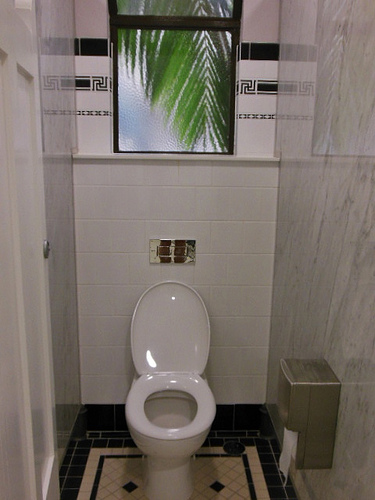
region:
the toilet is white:
[96, 273, 212, 477]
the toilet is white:
[142, 374, 202, 494]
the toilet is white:
[147, 280, 237, 480]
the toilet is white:
[166, 326, 221, 495]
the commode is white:
[126, 246, 218, 497]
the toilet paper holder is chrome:
[275, 338, 345, 494]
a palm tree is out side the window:
[114, 6, 244, 165]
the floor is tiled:
[85, 441, 134, 498]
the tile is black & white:
[84, 445, 134, 496]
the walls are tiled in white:
[87, 222, 128, 295]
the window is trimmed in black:
[102, 10, 248, 173]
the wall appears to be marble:
[310, 141, 364, 336]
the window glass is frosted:
[127, 39, 216, 162]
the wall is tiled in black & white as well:
[76, 23, 110, 146]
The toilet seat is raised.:
[118, 276, 236, 379]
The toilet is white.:
[112, 276, 233, 497]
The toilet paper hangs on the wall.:
[262, 422, 303, 492]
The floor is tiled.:
[193, 413, 294, 499]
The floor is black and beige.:
[192, 421, 283, 498]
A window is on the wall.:
[92, 1, 251, 168]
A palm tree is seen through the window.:
[117, 0, 241, 156]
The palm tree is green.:
[115, 1, 236, 149]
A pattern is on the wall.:
[231, 34, 281, 130]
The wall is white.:
[69, 159, 280, 240]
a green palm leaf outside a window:
[117, 0, 235, 150]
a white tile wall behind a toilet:
[80, 160, 265, 375]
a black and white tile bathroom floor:
[75, 430, 280, 494]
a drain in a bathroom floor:
[218, 436, 248, 453]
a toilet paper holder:
[270, 353, 334, 479]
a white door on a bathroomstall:
[2, 2, 62, 498]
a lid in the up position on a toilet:
[127, 279, 210, 376]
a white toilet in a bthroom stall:
[116, 279, 223, 498]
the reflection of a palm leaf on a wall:
[303, 4, 365, 165]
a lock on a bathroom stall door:
[36, 237, 56, 261]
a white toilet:
[123, 280, 218, 499]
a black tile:
[209, 478, 224, 493]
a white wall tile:
[104, 216, 151, 255]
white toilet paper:
[275, 420, 295, 491]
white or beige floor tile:
[223, 457, 239, 471]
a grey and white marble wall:
[300, 216, 368, 281]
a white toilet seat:
[124, 371, 214, 439]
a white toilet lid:
[127, 277, 210, 373]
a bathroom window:
[102, 0, 238, 152]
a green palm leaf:
[110, 0, 232, 154]